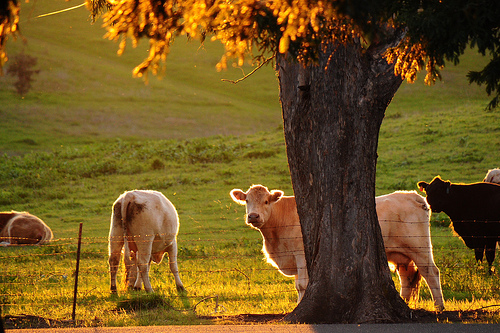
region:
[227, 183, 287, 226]
The cow is facing forward.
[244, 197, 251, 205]
The cows left eye is black.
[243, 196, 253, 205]
The cows left eye is small.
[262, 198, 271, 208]
The cows right eye is black.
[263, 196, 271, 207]
The cows right eye is small.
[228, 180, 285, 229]
The cows face is white.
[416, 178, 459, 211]
The cow has a black face.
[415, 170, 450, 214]
The cow has a orange tag on its ear.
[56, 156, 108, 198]
The grass in the background is green.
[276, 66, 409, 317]
The tree trunk in the forefront is brown.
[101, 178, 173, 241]
the cow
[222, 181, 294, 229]
a white cow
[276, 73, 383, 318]
a tree trunk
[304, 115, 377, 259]
bark on the tree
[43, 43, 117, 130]
a field of grass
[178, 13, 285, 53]
brown leaves on the tree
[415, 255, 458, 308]
the cows leg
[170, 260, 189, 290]
front leg of the cow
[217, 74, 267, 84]
a tree branch on the tree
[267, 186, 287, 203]
the cows ear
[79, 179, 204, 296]
A white cow in the field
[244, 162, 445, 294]
A white cow in the field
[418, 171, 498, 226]
A black cow in the field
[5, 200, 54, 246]
A brown cow in the field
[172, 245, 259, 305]
A green grass field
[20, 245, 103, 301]
A green grass field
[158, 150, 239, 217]
A green grass field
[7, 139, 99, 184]
A green grass field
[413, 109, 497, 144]
A green grass field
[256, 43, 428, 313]
A fat tree stem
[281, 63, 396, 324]
tree bark on ground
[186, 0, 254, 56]
leaves on the tree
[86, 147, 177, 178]
green grass on the ground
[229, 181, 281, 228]
head of beige cow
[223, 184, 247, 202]
right ear of the cow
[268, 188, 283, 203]
left ear of the horse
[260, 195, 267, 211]
left eye of the cow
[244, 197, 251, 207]
right eye of the cow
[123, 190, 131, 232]
tail on the cow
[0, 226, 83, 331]
small wire fence around animals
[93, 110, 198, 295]
the back of a cow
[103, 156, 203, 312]
cow eating grass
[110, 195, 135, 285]
white cow tail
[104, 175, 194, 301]
the back of a white cow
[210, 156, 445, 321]
cow standing next to a tree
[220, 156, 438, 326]
white cow standing next to a tree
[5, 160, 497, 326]
five cows in a field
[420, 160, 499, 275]
part of a black cow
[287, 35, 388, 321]
large tree trunk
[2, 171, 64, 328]
cow sitting in a field behind a wire fence